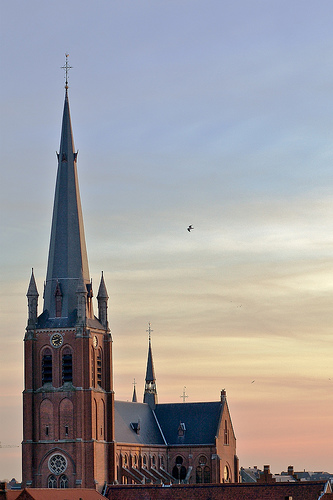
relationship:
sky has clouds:
[2, 1, 319, 474] [228, 210, 327, 362]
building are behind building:
[0, 52, 333, 499] [0, 52, 333, 499]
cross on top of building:
[60, 51, 74, 85] [2, 52, 329, 499]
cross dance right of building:
[178, 386, 190, 404] [132, 315, 185, 483]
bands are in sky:
[2, 351, 326, 470] [154, 200, 270, 300]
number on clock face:
[51, 337, 64, 348] [52, 333, 62, 347]